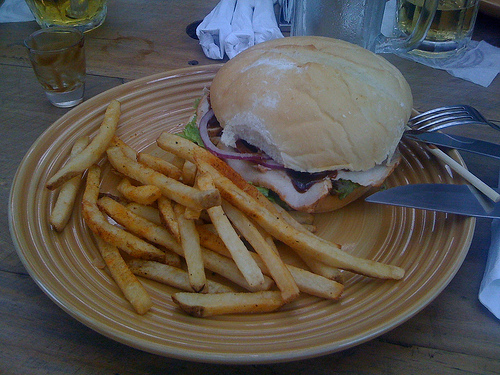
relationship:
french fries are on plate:
[45, 99, 405, 315] [8, 64, 476, 364]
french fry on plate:
[47, 100, 121, 191] [8, 64, 476, 364]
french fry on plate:
[49, 136, 89, 231] [8, 64, 476, 364]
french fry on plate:
[172, 289, 286, 317] [8, 64, 476, 364]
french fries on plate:
[191, 156, 406, 285] [8, 64, 476, 364]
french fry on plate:
[106, 146, 222, 210] [8, 64, 476, 364]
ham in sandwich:
[196, 91, 403, 214] [175, 35, 414, 214]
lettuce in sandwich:
[174, 97, 359, 210] [175, 35, 414, 214]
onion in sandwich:
[200, 108, 285, 170] [175, 35, 414, 214]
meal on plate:
[46, 36, 413, 318] [8, 64, 476, 364]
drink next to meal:
[24, 27, 86, 109] [46, 36, 413, 318]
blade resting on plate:
[364, 183, 499, 219] [8, 64, 476, 364]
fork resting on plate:
[407, 105, 499, 133] [8, 64, 476, 364]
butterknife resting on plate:
[401, 129, 499, 160] [8, 64, 476, 364]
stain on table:
[99, 35, 162, 63] [1, 1, 500, 374]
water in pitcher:
[294, 1, 386, 49] [291, 1, 439, 56]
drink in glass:
[25, 31, 85, 94] [25, 26, 86, 110]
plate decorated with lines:
[8, 64, 476, 364] [8, 63, 476, 366]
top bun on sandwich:
[209, 36, 413, 173] [175, 35, 414, 214]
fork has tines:
[407, 105, 499, 133] [408, 104, 474, 132]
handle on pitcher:
[376, 1, 438, 54] [291, 1, 439, 56]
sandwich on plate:
[175, 35, 414, 214] [8, 64, 476, 364]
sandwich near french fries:
[175, 35, 414, 214] [45, 99, 405, 315]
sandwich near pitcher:
[175, 35, 414, 214] [291, 1, 439, 56]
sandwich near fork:
[175, 35, 414, 214] [407, 105, 499, 133]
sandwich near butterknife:
[175, 35, 414, 214] [401, 129, 499, 160]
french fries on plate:
[45, 99, 405, 315] [8, 64, 476, 364]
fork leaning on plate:
[407, 105, 499, 133] [8, 64, 476, 364]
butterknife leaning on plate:
[401, 129, 499, 160] [8, 64, 476, 364]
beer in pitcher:
[397, 1, 474, 39] [394, 1, 479, 59]